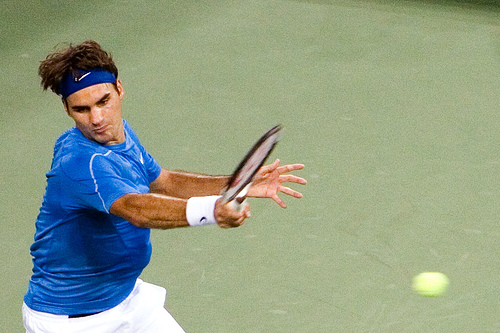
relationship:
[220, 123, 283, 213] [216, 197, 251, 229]
tennis racket in hand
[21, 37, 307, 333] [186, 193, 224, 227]
man has wrist guard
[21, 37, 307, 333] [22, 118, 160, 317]
man has t-shirt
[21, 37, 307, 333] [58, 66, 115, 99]
man has headband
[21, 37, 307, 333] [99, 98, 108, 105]
man has left eye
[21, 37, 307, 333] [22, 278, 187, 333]
man has shorts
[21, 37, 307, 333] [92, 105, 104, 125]
man has nose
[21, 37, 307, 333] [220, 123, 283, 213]
man swinging tennis racket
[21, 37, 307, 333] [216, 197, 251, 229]
man has hand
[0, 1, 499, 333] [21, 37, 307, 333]
tennis court under man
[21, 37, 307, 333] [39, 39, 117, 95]
man has hair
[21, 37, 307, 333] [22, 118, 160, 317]
man wearing t-shirt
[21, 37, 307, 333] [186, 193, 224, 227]
man wearing wrist guard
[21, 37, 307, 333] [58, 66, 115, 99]
man wearing headband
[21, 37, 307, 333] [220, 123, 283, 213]
man holding tennis racket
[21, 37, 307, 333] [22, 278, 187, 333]
man wearing shorts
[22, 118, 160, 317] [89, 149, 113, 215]
t-shirt has stripe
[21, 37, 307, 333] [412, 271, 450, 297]
man hitting tennis ball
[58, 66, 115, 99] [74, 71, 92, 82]
headband has swoosh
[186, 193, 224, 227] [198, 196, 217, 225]
wrist guard on right wrist